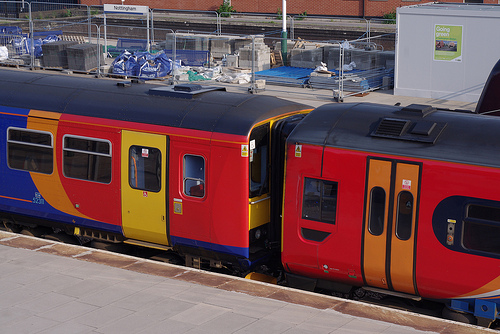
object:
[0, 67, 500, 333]
train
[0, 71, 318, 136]
roof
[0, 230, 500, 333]
ground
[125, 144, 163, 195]
window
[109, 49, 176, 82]
bags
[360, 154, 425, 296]
door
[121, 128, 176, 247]
door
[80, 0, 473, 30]
roof